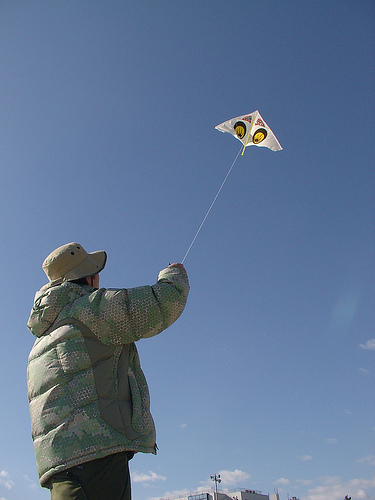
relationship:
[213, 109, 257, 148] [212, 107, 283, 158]
left side of kite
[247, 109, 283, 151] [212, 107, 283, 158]
right side of kite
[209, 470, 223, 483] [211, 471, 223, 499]
top of a speaker pole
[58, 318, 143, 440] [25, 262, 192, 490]
part of jacket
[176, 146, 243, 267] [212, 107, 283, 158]
string of kite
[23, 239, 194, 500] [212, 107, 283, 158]
person flying a kite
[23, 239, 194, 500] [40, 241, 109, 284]
person wearing a top hat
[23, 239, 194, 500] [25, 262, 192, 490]
person wearing a jacket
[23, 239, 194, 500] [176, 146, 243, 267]
person holding string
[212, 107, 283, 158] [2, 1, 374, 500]
kite floating in air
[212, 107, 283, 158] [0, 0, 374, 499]
kite flying in sky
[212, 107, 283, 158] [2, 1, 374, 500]
kite flying in air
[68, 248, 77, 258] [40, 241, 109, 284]
hole inside top hat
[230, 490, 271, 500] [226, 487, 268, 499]
top of a building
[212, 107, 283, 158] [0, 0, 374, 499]
kite floating in sky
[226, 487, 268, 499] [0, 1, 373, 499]
building standing in background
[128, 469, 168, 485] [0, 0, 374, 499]
cloud floating in sky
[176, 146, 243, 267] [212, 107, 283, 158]
string hanging on kite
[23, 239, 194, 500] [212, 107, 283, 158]
person with a kite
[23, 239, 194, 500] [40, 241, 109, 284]
person with a top hat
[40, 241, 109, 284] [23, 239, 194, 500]
top hat on top of person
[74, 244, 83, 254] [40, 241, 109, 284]
hole on top of top hat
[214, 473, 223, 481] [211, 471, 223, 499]
speaker on top of a speaker pole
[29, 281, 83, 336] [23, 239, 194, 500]
hood of person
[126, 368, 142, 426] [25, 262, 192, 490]
pocket of a jacket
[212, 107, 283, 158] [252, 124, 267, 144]
kite has eye